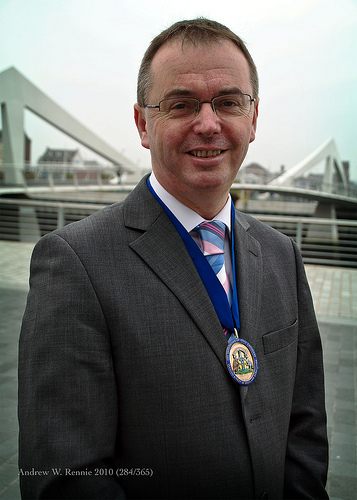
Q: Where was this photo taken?
A: France.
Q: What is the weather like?
A: Overcast.